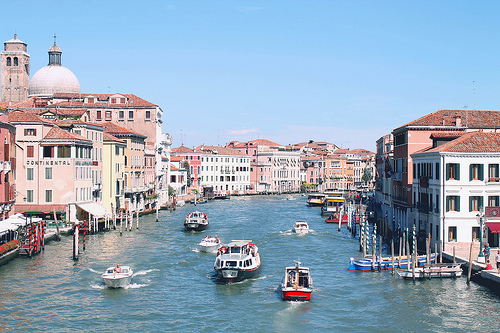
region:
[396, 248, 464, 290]
boat in the water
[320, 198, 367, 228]
boat in the water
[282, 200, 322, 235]
boat in the water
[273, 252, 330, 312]
boat in the water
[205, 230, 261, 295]
boat in the water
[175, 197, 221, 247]
boat in the water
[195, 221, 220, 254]
boat in the water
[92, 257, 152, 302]
boat in the water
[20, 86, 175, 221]
tall buildings near water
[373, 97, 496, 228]
tall buildings near water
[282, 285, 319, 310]
bottom of the boat is red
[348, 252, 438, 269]
blue boat by the dock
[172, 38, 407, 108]
sky is clear this day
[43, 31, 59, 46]
cross on top of building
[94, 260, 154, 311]
boat moving on water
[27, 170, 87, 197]
the building is pink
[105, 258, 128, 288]
man has red on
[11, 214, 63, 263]
red and black marker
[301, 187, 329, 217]
orange and white boat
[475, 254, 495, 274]
person with red on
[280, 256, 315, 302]
A small red and white boat going away from the camera.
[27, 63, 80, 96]
A white dome on a building.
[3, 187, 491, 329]
Blue body of water.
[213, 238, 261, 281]
The largest black and white boat in the water.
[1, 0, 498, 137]
Mostly blue sky.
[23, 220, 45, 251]
Four pink and black striped poles in a row in the water.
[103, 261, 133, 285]
An all white boat coming towards the camera with a red shirt guy on the front.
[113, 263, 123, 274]
A guy in a red shirt on a white boat coming this way.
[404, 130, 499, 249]
The first three story right house with red roof.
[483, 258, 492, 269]
A dark haired person in bright red sitting down.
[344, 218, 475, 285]
Blue and white boats at dock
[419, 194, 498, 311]
Person in red sitting on dock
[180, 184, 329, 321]
Power boats in canal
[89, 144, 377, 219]
Pink and white buildings on canal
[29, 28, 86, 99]
Dome church steeple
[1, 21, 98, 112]
Bell tower and dome steeple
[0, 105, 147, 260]
Pink contenental buliding on canal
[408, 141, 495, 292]
White building on dock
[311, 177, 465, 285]
Canal boats at dock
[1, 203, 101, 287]
red striped canal pylons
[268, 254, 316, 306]
Boat in the water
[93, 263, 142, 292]
Boat in the water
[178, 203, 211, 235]
Boat in the water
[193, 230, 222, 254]
Boat in the water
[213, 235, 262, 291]
Boat in the water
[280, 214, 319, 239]
Boat in the water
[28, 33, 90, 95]
Dome on top of building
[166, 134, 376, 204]
Buidings in the background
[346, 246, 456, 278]
Boat near the dock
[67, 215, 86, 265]
Pole in the water